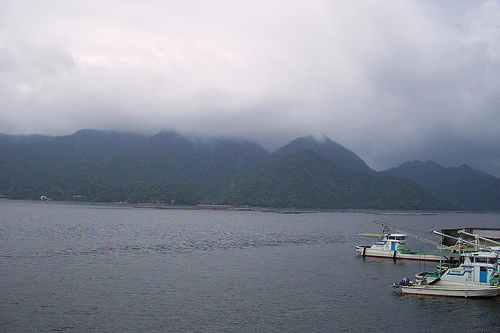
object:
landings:
[126, 202, 497, 218]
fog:
[0, 0, 497, 163]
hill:
[382, 159, 498, 197]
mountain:
[271, 129, 383, 171]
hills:
[383, 157, 499, 214]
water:
[0, 197, 497, 332]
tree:
[264, 155, 344, 198]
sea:
[0, 200, 498, 332]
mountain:
[0, 124, 148, 190]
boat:
[392, 245, 500, 297]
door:
[479, 265, 488, 283]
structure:
[441, 227, 500, 245]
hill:
[12, 126, 244, 196]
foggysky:
[0, 7, 494, 140]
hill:
[215, 147, 456, 210]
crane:
[371, 220, 496, 255]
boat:
[355, 219, 500, 266]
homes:
[0, 192, 17, 199]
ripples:
[167, 216, 337, 261]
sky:
[1, 2, 497, 178]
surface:
[4, 200, 500, 333]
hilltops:
[271, 131, 352, 148]